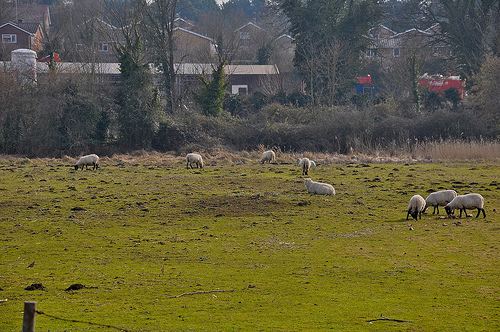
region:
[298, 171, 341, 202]
the sheep is resting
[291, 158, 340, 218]
the sheep is resting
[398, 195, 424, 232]
the sheep is eating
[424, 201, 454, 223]
the sheep is eating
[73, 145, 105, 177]
the sheep is eating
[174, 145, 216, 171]
the sheep is eating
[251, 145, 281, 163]
the sheep is eating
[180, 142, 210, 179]
This is a sheep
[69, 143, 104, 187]
This is a sheep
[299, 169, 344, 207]
This is a sheep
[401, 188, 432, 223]
This is a sheep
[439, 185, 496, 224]
This is a sheep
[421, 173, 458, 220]
This is a sheep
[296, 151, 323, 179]
This is a sheep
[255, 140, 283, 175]
This is a sheep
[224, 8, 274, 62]
This is a house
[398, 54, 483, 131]
This is a house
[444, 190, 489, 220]
A grazing sheep in a field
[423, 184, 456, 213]
A grazing sheep in a field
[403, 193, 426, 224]
A grazing sheep in a field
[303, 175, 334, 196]
A sheep laying in a field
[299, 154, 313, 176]
A grazing sheep in a field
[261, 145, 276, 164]
A grazing sheep in a field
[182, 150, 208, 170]
A grazing sheep in a field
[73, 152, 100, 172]
A grazing sheep in a field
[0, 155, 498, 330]
A large grassy field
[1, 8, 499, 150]
A row of trees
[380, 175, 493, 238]
animals on the grass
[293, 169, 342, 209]
animal laying on the grass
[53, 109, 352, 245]
many animals in the background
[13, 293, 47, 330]
pole in the foreground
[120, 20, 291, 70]
houses in the background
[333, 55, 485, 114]
red and blue structure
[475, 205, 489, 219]
back legs of the animal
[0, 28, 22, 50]
window on the building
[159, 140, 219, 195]
one animal in the grass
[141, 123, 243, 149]
bushes behind the animals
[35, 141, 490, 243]
a flock of sheep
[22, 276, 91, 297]
black rocks in the grass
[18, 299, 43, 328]
a wooden post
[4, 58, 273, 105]
a concrete building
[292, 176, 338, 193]
a sheep laying down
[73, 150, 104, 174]
a sheep eating grass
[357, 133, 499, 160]
brown died grass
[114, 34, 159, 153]
a vine covered tree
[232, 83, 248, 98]
a white door on a building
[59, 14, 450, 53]
houses in the distance